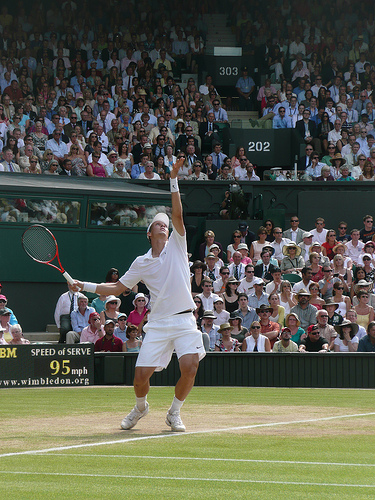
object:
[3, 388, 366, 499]
surface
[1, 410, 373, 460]
line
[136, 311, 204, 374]
shorts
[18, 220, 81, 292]
racquet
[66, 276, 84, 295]
hand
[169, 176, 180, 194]
band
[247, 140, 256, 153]
numbers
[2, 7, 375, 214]
background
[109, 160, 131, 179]
spectators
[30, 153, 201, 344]
serve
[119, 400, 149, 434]
shoes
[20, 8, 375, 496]
air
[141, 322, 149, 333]
ball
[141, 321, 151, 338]
pocket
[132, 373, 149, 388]
knees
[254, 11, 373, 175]
section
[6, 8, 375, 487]
stadium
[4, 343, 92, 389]
sign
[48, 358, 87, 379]
shows speed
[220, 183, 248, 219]
camera person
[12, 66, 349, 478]
match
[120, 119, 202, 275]
serve ball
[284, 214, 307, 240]
people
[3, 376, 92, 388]
advertisement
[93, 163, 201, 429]
man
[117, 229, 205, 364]
uniform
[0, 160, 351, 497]
game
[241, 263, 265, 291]
man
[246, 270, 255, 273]
sunglasses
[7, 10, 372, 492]
activity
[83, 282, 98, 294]
bands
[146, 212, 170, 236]
hat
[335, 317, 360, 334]
hat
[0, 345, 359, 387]
wall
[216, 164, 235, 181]
person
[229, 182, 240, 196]
camera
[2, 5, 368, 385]
stands